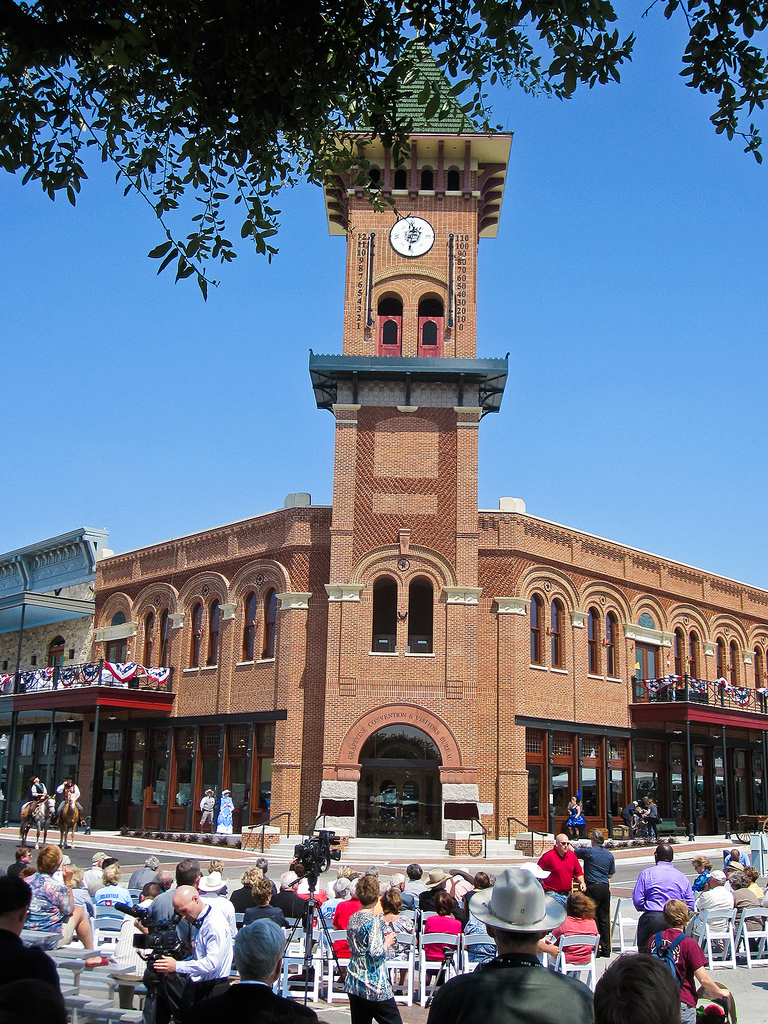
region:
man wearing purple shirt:
[631, 838, 695, 953]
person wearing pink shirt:
[425, 890, 462, 966]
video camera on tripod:
[274, 826, 355, 1022]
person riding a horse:
[19, 771, 59, 855]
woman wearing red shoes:
[17, 843, 111, 973]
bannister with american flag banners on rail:
[2, 658, 176, 692]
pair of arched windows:
[365, 567, 438, 658]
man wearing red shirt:
[535, 834, 588, 911]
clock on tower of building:
[386, 207, 438, 261]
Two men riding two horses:
[24, 777, 82, 850]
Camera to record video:
[270, 832, 357, 1016]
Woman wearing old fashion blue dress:
[569, 798, 587, 832]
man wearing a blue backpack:
[649, 900, 735, 1021]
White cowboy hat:
[468, 868, 568, 930]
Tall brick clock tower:
[328, 29, 488, 509]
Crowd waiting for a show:
[4, 845, 766, 977]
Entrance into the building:
[358, 758, 444, 840]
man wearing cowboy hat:
[431, 874, 602, 1023]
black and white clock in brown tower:
[376, 214, 441, 263]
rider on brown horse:
[22, 767, 60, 830]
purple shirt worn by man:
[645, 855, 681, 891]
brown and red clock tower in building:
[326, 154, 496, 834]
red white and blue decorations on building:
[83, 658, 185, 692]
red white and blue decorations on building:
[649, 666, 714, 707]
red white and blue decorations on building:
[22, 664, 102, 688]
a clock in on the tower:
[386, 214, 434, 260]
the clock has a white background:
[388, 214, 431, 258]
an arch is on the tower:
[336, 536, 472, 593]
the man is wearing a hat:
[467, 861, 572, 941]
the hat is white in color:
[465, 863, 568, 934]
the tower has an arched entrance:
[337, 693, 477, 842]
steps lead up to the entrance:
[255, 834, 535, 870]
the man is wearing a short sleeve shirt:
[535, 851, 583, 892]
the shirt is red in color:
[532, 849, 583, 893]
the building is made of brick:
[96, 58, 764, 841]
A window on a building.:
[526, 590, 546, 671]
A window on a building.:
[546, 590, 566, 673]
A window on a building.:
[588, 604, 605, 667]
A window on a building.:
[600, 604, 624, 675]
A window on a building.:
[264, 588, 277, 663]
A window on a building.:
[372, 566, 398, 658]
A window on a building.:
[408, 563, 427, 662]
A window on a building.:
[209, 599, 222, 680]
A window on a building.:
[182, 596, 208, 667]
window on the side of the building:
[180, 591, 207, 672]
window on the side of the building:
[209, 595, 222, 669]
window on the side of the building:
[259, 580, 277, 673]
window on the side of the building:
[371, 570, 398, 652]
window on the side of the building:
[529, 590, 544, 678]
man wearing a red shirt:
[538, 830, 588, 902]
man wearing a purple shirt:
[629, 840, 704, 950]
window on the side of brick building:
[206, 598, 220, 675]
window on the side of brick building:
[239, 589, 252, 672]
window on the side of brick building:
[260, 580, 277, 678]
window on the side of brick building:
[521, 595, 539, 679]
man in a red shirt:
[534, 828, 580, 903]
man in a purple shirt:
[620, 841, 696, 949]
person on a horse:
[53, 774, 94, 846]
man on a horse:
[21, 764, 57, 844]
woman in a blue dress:
[219, 785, 238, 836]